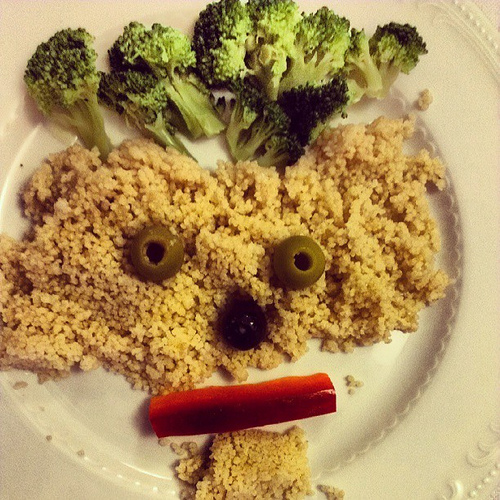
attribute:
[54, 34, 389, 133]
broccoli — tree-shaped, green, cooked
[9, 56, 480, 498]
plate — white, round, hallow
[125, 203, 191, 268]
olive — green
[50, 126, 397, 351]
rice — brown, face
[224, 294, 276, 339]
olive — black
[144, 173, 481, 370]
food — red, face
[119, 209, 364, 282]
olives — green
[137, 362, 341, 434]
pepper — red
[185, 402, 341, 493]
grain — tongue, loose